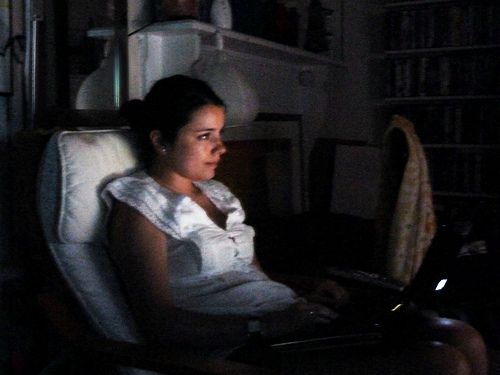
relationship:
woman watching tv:
[101, 72, 359, 363] [497, 87, 498, 252]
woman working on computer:
[101, 72, 359, 363] [258, 215, 464, 362]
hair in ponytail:
[111, 72, 229, 169] [118, 96, 143, 126]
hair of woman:
[111, 72, 229, 169] [101, 72, 359, 363]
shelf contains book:
[414, 141, 499, 158] [450, 102, 464, 144]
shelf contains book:
[358, 87, 498, 114] [413, 53, 430, 99]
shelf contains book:
[358, 87, 498, 114] [390, 59, 405, 99]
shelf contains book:
[358, 87, 498, 114] [400, 55, 417, 97]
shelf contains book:
[358, 87, 498, 114] [433, 51, 455, 95]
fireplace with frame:
[220, 126, 307, 247] [252, 110, 304, 219]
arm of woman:
[105, 203, 332, 343] [101, 72, 359, 363]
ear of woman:
[145, 129, 169, 153] [101, 72, 359, 363]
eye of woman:
[191, 129, 212, 141] [116, 70, 379, 373]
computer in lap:
[249, 213, 470, 357] [227, 294, 447, 363]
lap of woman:
[227, 294, 447, 363] [101, 72, 359, 363]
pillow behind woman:
[45, 132, 131, 339] [101, 72, 359, 363]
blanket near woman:
[383, 107, 438, 294] [112, 61, 306, 326]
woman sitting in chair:
[101, 72, 359, 363] [50, 125, 196, 372]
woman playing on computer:
[101, 72, 359, 363] [249, 213, 470, 357]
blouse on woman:
[100, 174, 299, 308] [101, 72, 359, 363]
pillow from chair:
[45, 132, 137, 245] [49, 115, 132, 358]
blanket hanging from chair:
[383, 114, 437, 287] [381, 120, 458, 286]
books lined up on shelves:
[376, 23, 496, 142] [368, 0, 499, 180]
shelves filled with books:
[373, 33, 492, 184] [360, 52, 499, 107]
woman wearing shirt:
[101, 72, 359, 363] [95, 163, 303, 316]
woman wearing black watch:
[101, 72, 359, 363] [243, 312, 265, 342]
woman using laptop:
[101, 72, 359, 363] [220, 202, 497, 373]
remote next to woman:
[318, 262, 394, 297] [101, 80, 360, 364]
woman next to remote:
[101, 80, 360, 364] [318, 262, 394, 297]